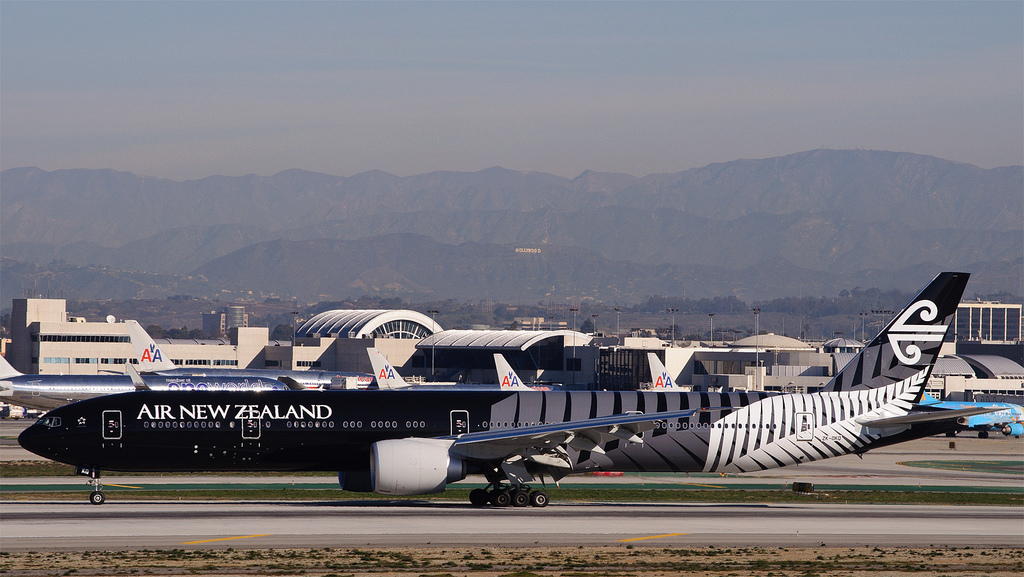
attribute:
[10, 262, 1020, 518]
plane — black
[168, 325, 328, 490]
plane — blue, gray